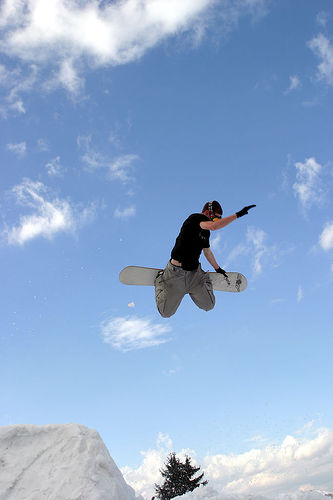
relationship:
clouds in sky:
[26, 3, 151, 51] [3, 7, 328, 191]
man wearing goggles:
[153, 197, 236, 314] [204, 201, 222, 219]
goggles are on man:
[204, 201, 222, 219] [153, 197, 236, 314]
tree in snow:
[154, 451, 204, 498] [140, 470, 330, 498]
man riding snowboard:
[153, 197, 254, 318] [115, 260, 253, 295]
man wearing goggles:
[153, 197, 254, 318] [202, 200, 223, 221]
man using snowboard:
[153, 197, 254, 318] [117, 257, 255, 298]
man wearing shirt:
[153, 197, 254, 318] [168, 213, 211, 265]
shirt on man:
[168, 213, 211, 265] [153, 197, 254, 318]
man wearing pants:
[153, 197, 254, 318] [153, 260, 215, 317]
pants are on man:
[153, 260, 215, 317] [153, 197, 254, 318]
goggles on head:
[204, 201, 222, 219] [178, 187, 227, 228]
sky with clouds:
[21, 65, 303, 436] [57, 261, 181, 367]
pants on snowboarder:
[137, 273, 246, 352] [100, 147, 253, 327]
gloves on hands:
[233, 200, 252, 229] [203, 188, 265, 237]